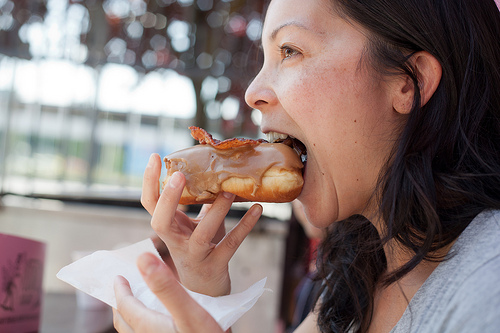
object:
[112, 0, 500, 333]
person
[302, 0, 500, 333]
hair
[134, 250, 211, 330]
thumb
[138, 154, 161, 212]
fingers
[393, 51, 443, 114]
ear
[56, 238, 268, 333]
napkin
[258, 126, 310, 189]
mouth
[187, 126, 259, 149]
chip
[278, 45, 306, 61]
left eye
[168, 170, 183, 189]
nail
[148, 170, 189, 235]
finger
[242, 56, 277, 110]
nose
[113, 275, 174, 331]
thumb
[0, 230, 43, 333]
sign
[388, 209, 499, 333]
shirt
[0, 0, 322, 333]
distance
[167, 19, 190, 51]
light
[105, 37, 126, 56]
light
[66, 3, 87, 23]
light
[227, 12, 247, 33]
light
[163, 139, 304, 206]
chocolate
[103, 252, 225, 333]
hand